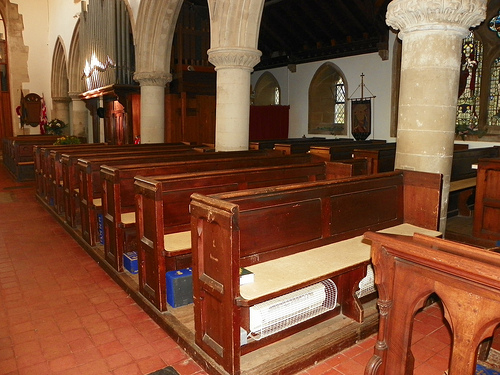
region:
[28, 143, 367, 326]
pews in a place of worship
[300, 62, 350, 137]
window with an arch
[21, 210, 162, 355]
floor of the building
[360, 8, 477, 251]
column inside the building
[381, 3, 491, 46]
decorative top of column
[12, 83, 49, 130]
flags on a table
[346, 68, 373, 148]
banner on the wall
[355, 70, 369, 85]
cross at top of banner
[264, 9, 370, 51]
rafters on the ceiling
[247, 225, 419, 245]
seat area of pews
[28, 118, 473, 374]
Row of brown and white seats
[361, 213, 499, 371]
Brown wooden decoration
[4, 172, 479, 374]
Red brick floor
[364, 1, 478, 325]
White column made of stone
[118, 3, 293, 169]
Brown and white arch inside building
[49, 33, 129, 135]
Light shining on wall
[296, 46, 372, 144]
Black and brown window on wall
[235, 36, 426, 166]
White part of wall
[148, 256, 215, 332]
Blue box under seat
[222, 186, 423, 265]
Two brown panels on back rest of seat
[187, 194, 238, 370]
brown wooden bench side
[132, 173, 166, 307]
brown wooden bench side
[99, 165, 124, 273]
brown wooden bench side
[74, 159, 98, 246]
brown wooden bench side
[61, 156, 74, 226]
brown wooden bench side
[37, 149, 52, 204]
brown wooden bench side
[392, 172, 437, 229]
brown wooden bench side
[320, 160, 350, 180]
brown wooden bench side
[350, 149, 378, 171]
brown wooden bench side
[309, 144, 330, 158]
brown wooden bench side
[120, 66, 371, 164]
this is a column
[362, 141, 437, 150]
this is a stone column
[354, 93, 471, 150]
the column is yellow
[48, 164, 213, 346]
this is a church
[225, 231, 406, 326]
these are church pews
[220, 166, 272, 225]
the pews are wooden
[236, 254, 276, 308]
this is a book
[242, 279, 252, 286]
the book is green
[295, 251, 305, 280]
the cushion is plush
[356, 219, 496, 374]
this is a church bench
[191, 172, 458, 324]
this is a church bench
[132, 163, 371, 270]
this is a church bench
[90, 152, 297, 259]
this is a church bench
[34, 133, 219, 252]
this is a church bench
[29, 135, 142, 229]
this is a church bench